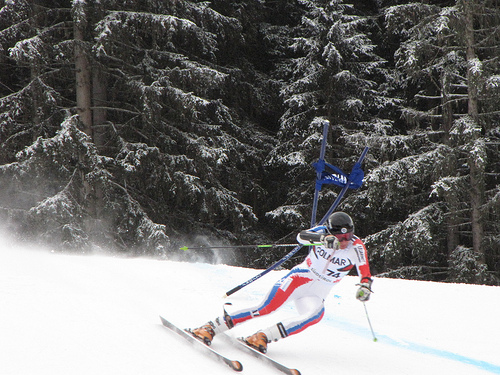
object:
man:
[179, 208, 376, 355]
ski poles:
[176, 239, 330, 252]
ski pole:
[176, 239, 326, 251]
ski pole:
[356, 300, 381, 344]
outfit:
[209, 227, 371, 341]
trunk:
[57, 14, 173, 154]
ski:
[302, 127, 373, 252]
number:
[327, 267, 338, 280]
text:
[327, 270, 338, 278]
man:
[193, 212, 370, 362]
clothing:
[215, 226, 371, 347]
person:
[191, 213, 373, 352]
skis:
[160, 312, 299, 374]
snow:
[13, 260, 145, 373]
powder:
[3, 175, 227, 271]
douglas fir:
[443, 20, 490, 280]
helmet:
[323, 210, 362, 232]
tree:
[336, 0, 498, 272]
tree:
[252, 0, 396, 272]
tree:
[5, 0, 279, 250]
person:
[180, 210, 377, 356]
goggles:
[326, 227, 354, 242]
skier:
[177, 207, 378, 366]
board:
[192, 300, 296, 374]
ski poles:
[357, 288, 377, 342]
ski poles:
[180, 242, 331, 249]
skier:
[186, 209, 371, 354]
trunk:
[428, 32, 497, 292]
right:
[429, 15, 496, 265]